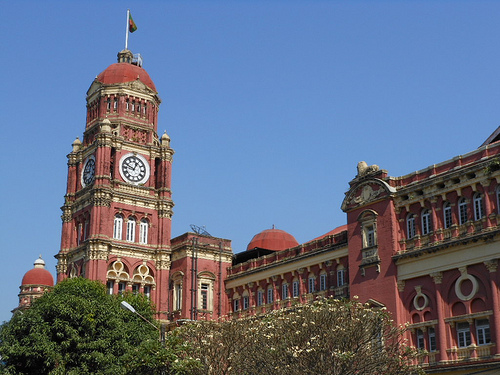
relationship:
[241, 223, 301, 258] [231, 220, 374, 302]
dome on top of building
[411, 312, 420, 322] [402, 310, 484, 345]
archway above window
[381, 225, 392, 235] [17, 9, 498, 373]
brick on building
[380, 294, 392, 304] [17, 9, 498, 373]
brick on building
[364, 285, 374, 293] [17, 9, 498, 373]
brick on building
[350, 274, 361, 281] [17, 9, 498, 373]
brick on building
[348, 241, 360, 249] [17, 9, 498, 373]
brick on building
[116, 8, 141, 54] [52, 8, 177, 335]
flag on building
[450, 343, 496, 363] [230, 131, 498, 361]
balcony attached to building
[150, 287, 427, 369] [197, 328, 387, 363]
flowers growing from tree